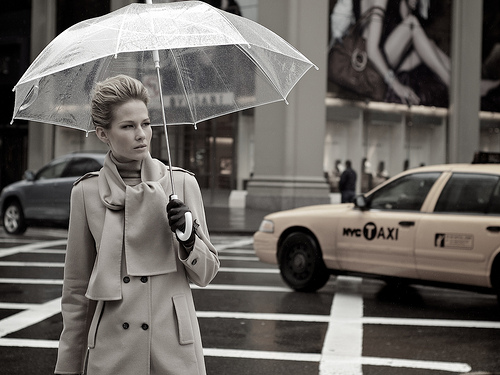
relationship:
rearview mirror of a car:
[346, 190, 371, 210] [248, 150, 498, 310]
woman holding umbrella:
[54, 72, 218, 372] [9, 1, 323, 244]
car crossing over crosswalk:
[251, 162, 500, 293] [3, 230, 484, 373]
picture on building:
[323, 0, 455, 117] [0, 2, 481, 214]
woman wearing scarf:
[54, 72, 218, 372] [85, 151, 178, 301]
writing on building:
[164, 91, 234, 110] [0, 2, 481, 214]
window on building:
[212, 108, 237, 194] [0, 2, 481, 214]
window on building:
[212, 108, 238, 142] [0, 2, 481, 214]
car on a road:
[251, 159, 484, 297] [1, 230, 500, 375]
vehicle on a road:
[0, 150, 108, 239] [1, 230, 500, 375]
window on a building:
[212, 108, 238, 142] [0, 2, 481, 214]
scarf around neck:
[85, 151, 178, 301] [106, 150, 146, 181]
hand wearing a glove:
[164, 197, 198, 234] [163, 198, 201, 259]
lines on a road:
[0, 238, 473, 373] [1, 230, 500, 375]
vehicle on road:
[2, 150, 108, 235] [1, 230, 500, 375]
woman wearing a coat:
[54, 72, 218, 372] [52, 154, 221, 373]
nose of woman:
[134, 124, 148, 142] [54, 72, 218, 372]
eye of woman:
[117, 122, 133, 128] [54, 72, 218, 372]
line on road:
[200, 344, 320, 361] [1, 234, 496, 373]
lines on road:
[360, 315, 499, 327] [1, 234, 496, 373]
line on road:
[187, 277, 292, 293] [1, 234, 496, 373]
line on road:
[2, 290, 62, 340] [1, 234, 496, 373]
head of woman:
[90, 73, 153, 156] [54, 72, 218, 372]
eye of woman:
[121, 119, 133, 134] [54, 72, 218, 372]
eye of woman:
[141, 117, 151, 131] [54, 72, 218, 372]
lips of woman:
[130, 144, 149, 153] [54, 72, 218, 372]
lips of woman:
[130, 140, 150, 151] [54, 72, 218, 372]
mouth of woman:
[132, 140, 149, 152] [54, 72, 218, 372]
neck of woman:
[108, 147, 138, 167] [54, 72, 218, 372]